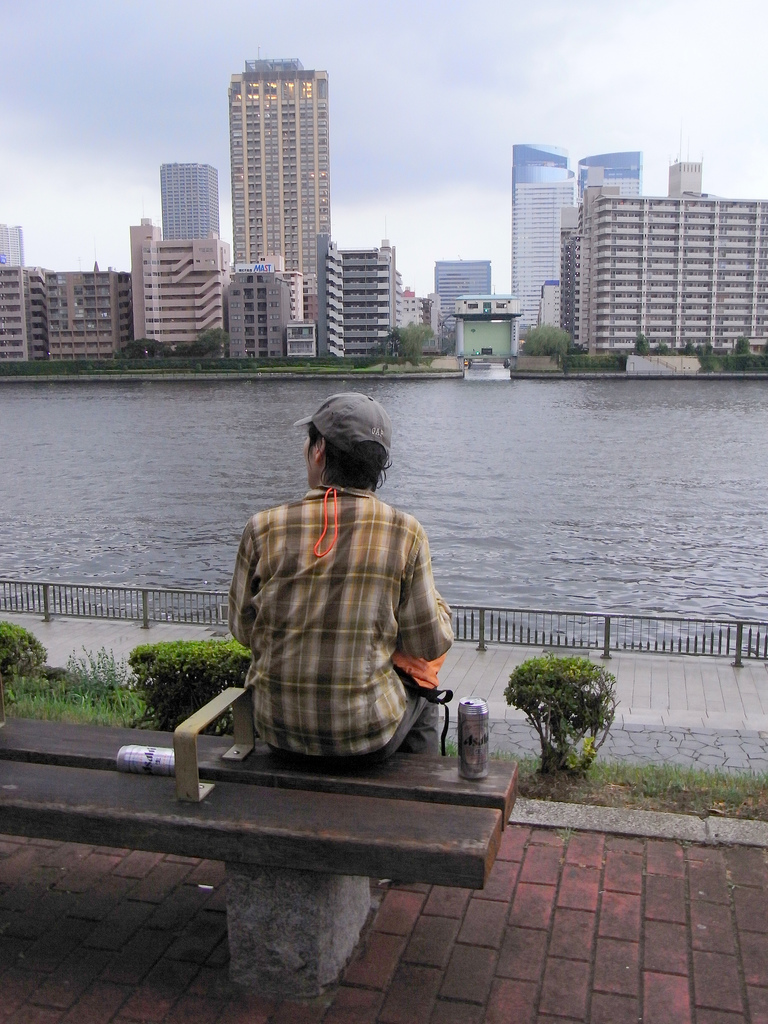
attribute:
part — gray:
[229, 865, 376, 994]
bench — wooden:
[20, 621, 572, 873]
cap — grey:
[260, 389, 399, 470]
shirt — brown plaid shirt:
[232, 497, 469, 768]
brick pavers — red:
[409, 195, 506, 372]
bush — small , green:
[500, 654, 625, 783]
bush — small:
[481, 622, 750, 860]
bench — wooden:
[33, 667, 661, 967]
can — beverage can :
[432, 664, 547, 823]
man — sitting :
[127, 362, 564, 778]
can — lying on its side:
[424, 661, 525, 788]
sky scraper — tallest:
[446, 49, 517, 160]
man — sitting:
[131, 358, 642, 864]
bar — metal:
[156, 664, 259, 816]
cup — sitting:
[443, 685, 511, 788]